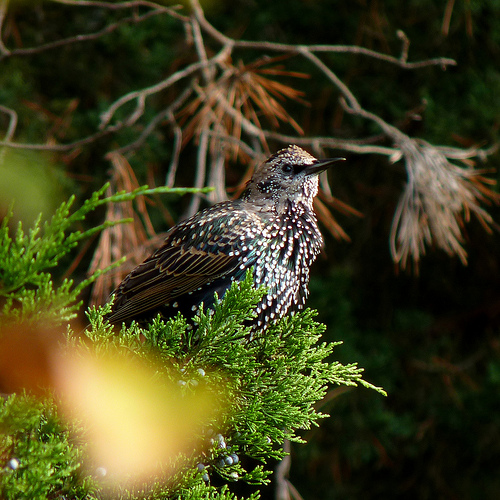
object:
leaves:
[186, 265, 389, 446]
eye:
[281, 163, 293, 174]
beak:
[305, 157, 346, 176]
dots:
[236, 226, 290, 274]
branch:
[296, 43, 499, 276]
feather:
[75, 178, 325, 341]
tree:
[0, 180, 387, 499]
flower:
[342, 102, 500, 280]